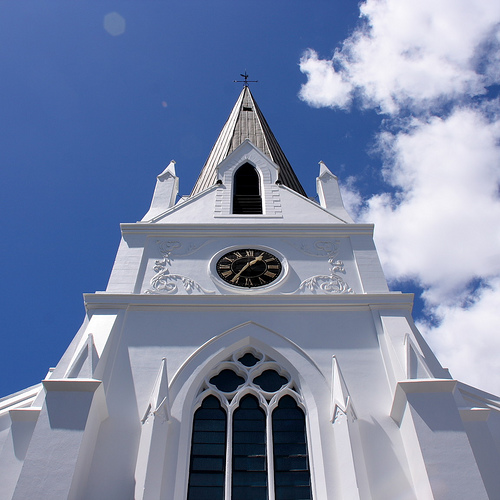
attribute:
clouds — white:
[430, 199, 494, 254]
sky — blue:
[6, 3, 499, 422]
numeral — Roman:
[258, 249, 283, 281]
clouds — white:
[284, 2, 499, 379]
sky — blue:
[0, 2, 497, 380]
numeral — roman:
[240, 271, 256, 288]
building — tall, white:
[5, 68, 499, 498]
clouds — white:
[300, 2, 497, 116]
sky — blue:
[1, 1, 498, 71]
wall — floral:
[127, 164, 360, 333]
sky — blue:
[29, 30, 184, 115]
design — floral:
[285, 251, 357, 295]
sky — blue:
[16, 11, 481, 311]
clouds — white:
[375, 69, 454, 160]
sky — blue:
[267, 10, 479, 161]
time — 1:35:
[199, 240, 280, 291]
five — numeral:
[256, 273, 265, 284]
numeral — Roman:
[244, 252, 253, 262]